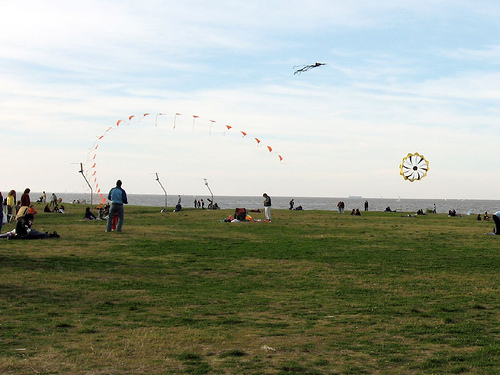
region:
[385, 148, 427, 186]
kite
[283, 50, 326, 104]
blue kite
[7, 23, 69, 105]
white clouds in blue sky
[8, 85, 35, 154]
white clouds in blue sky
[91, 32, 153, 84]
white clouds in blue sky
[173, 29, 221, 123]
white clouds in blue sky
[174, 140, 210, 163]
white clouds in blue sky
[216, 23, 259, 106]
white clouds in blue sky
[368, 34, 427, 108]
white clouds in blue sky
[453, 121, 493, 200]
white clouds in blue sky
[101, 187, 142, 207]
the jacket is blue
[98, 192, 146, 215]
the jacket is blue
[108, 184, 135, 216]
the jacket is blue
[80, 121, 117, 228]
the kites are orange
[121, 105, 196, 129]
the kites are orange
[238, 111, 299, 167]
the kites are orange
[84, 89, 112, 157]
the kites are orange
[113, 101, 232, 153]
the kites are orange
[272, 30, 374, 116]
the kite is flying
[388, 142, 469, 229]
the kite is flying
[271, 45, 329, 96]
the kite is flying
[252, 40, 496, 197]
the kite is flying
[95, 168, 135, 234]
the man is looking up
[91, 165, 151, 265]
the man is looking up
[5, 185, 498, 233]
many people flying kites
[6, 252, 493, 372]
lots of dry grass in the field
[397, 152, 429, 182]
a round kite flying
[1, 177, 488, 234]
many people enyoing a sunny afternoon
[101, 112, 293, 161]
a long orange tail of a kite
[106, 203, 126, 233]
a man in a blue jeans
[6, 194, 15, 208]
a woman ina a yellow sweater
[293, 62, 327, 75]
a kite flying high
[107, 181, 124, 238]
a man flying a kite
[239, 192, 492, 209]
a quite gray sea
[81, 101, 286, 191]
a banner floating away in the wind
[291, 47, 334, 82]
a kite with tassels flying in the sky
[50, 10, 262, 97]
a mostly cloudy sky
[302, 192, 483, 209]
a grey lake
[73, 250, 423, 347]
green and brown grass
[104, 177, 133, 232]
a man with a blue long sleeve shirt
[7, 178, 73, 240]
people sitting on a lake front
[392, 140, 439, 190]
an circular object flying in the sky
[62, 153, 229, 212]
a row of odd looking poles sticking out of the ground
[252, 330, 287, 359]
a piece of garbage on the ground